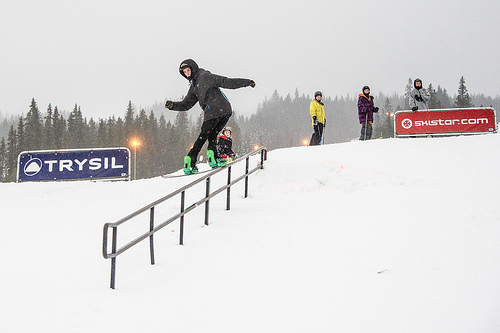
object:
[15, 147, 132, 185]
sign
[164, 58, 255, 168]
hood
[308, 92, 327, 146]
hood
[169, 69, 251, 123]
jacket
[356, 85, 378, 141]
person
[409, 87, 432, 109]
jacket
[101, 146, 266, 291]
rail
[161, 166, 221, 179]
snow board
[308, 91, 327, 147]
person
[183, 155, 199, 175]
shoes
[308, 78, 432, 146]
people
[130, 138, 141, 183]
lamppost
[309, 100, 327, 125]
jacket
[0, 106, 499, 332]
area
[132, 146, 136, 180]
pole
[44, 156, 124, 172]
writing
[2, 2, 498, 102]
sky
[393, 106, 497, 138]
sign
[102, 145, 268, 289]
banisters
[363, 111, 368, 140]
poles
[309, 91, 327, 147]
man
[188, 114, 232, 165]
pants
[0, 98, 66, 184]
pines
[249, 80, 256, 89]
gloves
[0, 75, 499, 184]
forest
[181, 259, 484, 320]
snow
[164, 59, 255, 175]
man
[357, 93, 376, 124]
jacket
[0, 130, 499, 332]
hill